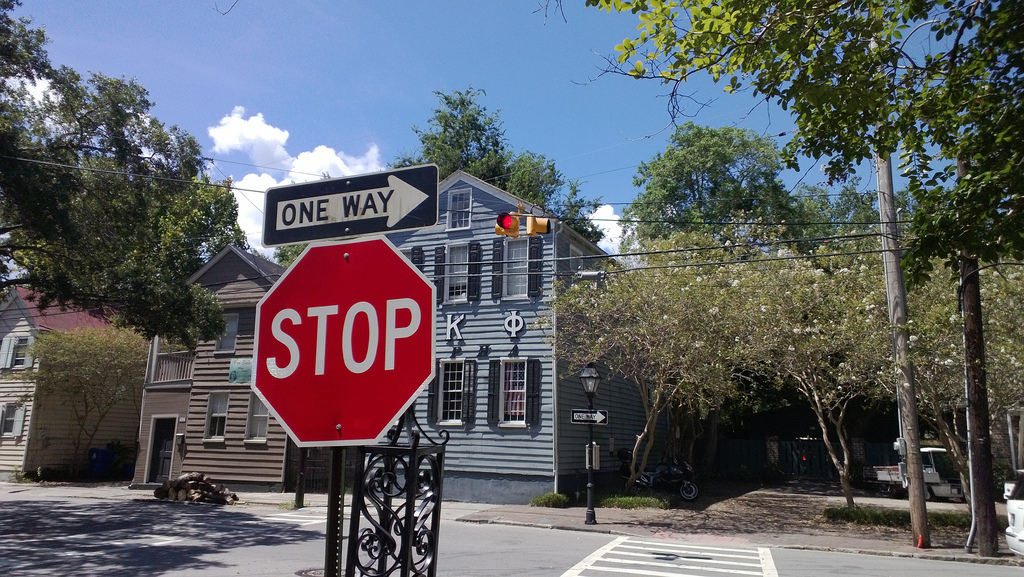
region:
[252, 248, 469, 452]
a red sign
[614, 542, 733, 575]
the cross walk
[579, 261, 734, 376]
the tree braches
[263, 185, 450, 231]
a black and white sign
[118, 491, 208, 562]
the shadow on the street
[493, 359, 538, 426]
a window on the house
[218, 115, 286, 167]
a cloud in the sky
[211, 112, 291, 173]
the cloud is white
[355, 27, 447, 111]
the sky is clear and blue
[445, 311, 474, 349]
a letter on the house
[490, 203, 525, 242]
a red traffic light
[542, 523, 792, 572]
white lines on the road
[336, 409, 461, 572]
a wrought iron decoration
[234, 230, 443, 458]
a red and white sign.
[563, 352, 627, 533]
a lamp post on the sidewalk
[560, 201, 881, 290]
wires attached to a post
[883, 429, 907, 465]
a power meter on a pole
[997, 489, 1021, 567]
the back of a parked car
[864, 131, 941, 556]
a tall electric pole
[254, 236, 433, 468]
a red and white sign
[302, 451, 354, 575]
a pole that is long and black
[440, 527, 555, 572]
a street that is grey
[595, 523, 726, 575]
a bunch of stripes on the road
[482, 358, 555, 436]
a window on a house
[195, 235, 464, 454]
red and white stop sign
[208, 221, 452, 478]
red and white sign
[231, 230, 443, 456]
stop sign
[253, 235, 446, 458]
white and red stop sign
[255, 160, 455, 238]
black and white sign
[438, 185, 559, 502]
old building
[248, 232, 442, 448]
a red and white traffic sign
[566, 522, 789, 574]
white lines painted on a street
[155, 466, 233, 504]
a pile of fire wood on the ground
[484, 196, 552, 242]
two yellow traffic lights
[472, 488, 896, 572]
a concrete sidewalk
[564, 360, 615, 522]
a black metal street light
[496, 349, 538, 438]
A window on a building.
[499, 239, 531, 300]
A window on a building.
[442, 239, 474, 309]
A window on a building.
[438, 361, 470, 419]
A window on a building.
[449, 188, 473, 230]
A window on a building.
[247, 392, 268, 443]
A window on a building.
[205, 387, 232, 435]
A window on a building.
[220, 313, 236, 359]
A window on a building.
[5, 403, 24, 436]
A window on a building.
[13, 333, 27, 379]
A window on a building.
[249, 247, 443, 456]
Red and white sign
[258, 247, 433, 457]
Red and white stop sign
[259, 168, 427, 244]
Black and white sign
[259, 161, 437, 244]
Black and white street sign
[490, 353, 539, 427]
Window of a house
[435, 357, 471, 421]
Window of a house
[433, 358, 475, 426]
Window of a blue house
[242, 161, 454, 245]
black and white one way sign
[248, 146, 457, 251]
black and white one way sign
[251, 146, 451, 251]
black and white one way sign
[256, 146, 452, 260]
black and white one way sign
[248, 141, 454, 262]
black and white one way sign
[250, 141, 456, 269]
black and white one way sign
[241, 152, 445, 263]
black and white one way sign